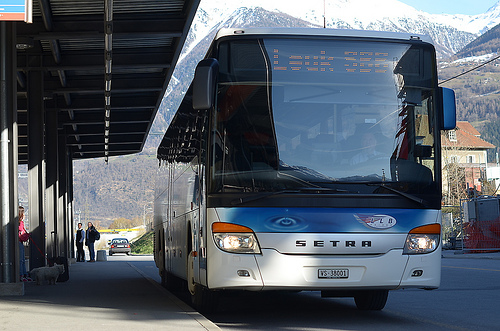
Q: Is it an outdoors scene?
A: Yes, it is outdoors.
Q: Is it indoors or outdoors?
A: It is outdoors.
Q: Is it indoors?
A: No, it is outdoors.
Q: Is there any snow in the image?
A: Yes, there is snow.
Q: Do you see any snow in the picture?
A: Yes, there is snow.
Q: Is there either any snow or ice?
A: Yes, there is snow.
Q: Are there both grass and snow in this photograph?
A: No, there is snow but no grass.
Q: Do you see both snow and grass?
A: No, there is snow but no grass.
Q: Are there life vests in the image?
A: No, there are no life vests.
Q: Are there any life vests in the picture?
A: No, there are no life vests.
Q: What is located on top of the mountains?
A: The snow is on top of the mountains.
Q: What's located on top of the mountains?
A: The snow is on top of the mountains.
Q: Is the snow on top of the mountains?
A: Yes, the snow is on top of the mountains.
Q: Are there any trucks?
A: No, there are no trucks.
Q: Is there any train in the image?
A: No, there are no trains.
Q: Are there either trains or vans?
A: No, there are no trains or vans.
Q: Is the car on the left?
A: Yes, the car is on the left of the image.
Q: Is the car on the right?
A: No, the car is on the left of the image.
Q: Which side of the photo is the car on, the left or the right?
A: The car is on the left of the image.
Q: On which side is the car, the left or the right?
A: The car is on the left of the image.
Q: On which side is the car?
A: The car is on the left of the image.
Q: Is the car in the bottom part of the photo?
A: Yes, the car is in the bottom of the image.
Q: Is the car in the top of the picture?
A: No, the car is in the bottom of the image.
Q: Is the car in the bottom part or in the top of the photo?
A: The car is in the bottom of the image.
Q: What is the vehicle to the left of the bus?
A: The vehicle is a car.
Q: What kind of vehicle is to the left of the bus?
A: The vehicle is a car.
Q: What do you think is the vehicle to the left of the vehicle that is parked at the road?
A: The vehicle is a car.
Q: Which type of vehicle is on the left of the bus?
A: The vehicle is a car.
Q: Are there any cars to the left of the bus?
A: Yes, there is a car to the left of the bus.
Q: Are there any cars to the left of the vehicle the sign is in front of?
A: Yes, there is a car to the left of the bus.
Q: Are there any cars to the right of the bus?
A: No, the car is to the left of the bus.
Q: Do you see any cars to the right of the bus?
A: No, the car is to the left of the bus.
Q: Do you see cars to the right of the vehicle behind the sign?
A: No, the car is to the left of the bus.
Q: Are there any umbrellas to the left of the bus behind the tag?
A: No, there is a car to the left of the bus.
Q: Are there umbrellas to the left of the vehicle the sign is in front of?
A: No, there is a car to the left of the bus.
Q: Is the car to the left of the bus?
A: Yes, the car is to the left of the bus.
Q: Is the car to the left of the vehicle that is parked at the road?
A: Yes, the car is to the left of the bus.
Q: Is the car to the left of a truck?
A: No, the car is to the left of the bus.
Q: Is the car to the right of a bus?
A: No, the car is to the left of a bus.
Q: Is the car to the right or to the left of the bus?
A: The car is to the left of the bus.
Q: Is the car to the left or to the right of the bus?
A: The car is to the left of the bus.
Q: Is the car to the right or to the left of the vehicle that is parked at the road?
A: The car is to the left of the bus.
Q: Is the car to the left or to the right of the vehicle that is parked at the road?
A: The car is to the left of the bus.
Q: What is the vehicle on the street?
A: The vehicle is a car.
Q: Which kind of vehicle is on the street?
A: The vehicle is a car.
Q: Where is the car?
A: The car is on the street.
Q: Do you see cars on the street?
A: Yes, there is a car on the street.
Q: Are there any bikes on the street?
A: No, there is a car on the street.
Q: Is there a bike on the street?
A: No, there is a car on the street.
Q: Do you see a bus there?
A: Yes, there is a bus.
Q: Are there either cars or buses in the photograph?
A: Yes, there is a bus.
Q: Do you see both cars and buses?
A: Yes, there are both a bus and a car.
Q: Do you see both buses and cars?
A: Yes, there are both a bus and a car.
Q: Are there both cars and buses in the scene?
A: Yes, there are both a bus and a car.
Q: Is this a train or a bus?
A: This is a bus.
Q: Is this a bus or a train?
A: This is a bus.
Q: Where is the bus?
A: The bus is on the road.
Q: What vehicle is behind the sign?
A: The vehicle is a bus.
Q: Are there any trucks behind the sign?
A: No, there is a bus behind the sign.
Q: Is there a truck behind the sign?
A: No, there is a bus behind the sign.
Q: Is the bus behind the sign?
A: Yes, the bus is behind the sign.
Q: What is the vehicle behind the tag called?
A: The vehicle is a bus.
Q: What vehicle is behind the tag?
A: The vehicle is a bus.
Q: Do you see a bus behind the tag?
A: Yes, there is a bus behind the tag.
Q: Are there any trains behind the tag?
A: No, there is a bus behind the tag.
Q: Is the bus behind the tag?
A: Yes, the bus is behind the tag.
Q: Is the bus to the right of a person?
A: Yes, the bus is to the right of a person.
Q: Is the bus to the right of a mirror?
A: No, the bus is to the right of a person.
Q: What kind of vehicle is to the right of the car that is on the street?
A: The vehicle is a bus.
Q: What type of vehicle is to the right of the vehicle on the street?
A: The vehicle is a bus.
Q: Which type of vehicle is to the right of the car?
A: The vehicle is a bus.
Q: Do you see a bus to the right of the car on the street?
A: Yes, there is a bus to the right of the car.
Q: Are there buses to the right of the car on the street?
A: Yes, there is a bus to the right of the car.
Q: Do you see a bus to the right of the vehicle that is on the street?
A: Yes, there is a bus to the right of the car.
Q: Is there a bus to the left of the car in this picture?
A: No, the bus is to the right of the car.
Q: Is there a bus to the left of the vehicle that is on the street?
A: No, the bus is to the right of the car.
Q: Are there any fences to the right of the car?
A: No, there is a bus to the right of the car.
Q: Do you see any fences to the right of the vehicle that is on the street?
A: No, there is a bus to the right of the car.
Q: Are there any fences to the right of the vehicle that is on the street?
A: No, there is a bus to the right of the car.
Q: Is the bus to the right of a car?
A: Yes, the bus is to the right of a car.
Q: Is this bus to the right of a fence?
A: No, the bus is to the right of a car.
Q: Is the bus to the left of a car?
A: No, the bus is to the right of a car.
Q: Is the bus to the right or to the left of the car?
A: The bus is to the right of the car.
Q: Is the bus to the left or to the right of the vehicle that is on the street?
A: The bus is to the right of the car.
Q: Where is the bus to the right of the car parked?
A: The bus is parked at the road.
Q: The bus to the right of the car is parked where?
A: The bus is parked at the road.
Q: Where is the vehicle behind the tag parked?
A: The bus is parked at the road.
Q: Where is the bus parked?
A: The bus is parked at the road.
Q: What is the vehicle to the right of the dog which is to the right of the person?
A: The vehicle is a bus.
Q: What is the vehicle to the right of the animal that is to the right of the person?
A: The vehicle is a bus.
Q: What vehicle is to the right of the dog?
A: The vehicle is a bus.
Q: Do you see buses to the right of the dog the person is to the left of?
A: Yes, there is a bus to the right of the dog.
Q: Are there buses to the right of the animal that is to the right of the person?
A: Yes, there is a bus to the right of the dog.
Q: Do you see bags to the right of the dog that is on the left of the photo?
A: No, there is a bus to the right of the dog.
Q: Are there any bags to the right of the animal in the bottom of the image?
A: No, there is a bus to the right of the dog.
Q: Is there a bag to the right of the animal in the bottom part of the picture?
A: No, there is a bus to the right of the dog.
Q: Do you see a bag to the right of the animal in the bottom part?
A: No, there is a bus to the right of the dog.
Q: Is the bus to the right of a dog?
A: Yes, the bus is to the right of a dog.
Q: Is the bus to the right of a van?
A: No, the bus is to the right of a dog.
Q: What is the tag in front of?
A: The tag is in front of the bus.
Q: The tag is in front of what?
A: The tag is in front of the bus.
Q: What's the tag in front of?
A: The tag is in front of the bus.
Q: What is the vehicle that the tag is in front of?
A: The vehicle is a bus.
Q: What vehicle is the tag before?
A: The tag is in front of the bus.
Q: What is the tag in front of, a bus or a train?
A: The tag is in front of a bus.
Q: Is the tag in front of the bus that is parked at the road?
A: Yes, the tag is in front of the bus.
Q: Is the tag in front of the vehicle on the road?
A: Yes, the tag is in front of the bus.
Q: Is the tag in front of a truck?
A: No, the tag is in front of the bus.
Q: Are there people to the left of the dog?
A: Yes, there is a person to the left of the dog.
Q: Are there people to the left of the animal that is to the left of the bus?
A: Yes, there is a person to the left of the dog.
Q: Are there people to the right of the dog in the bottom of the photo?
A: No, the person is to the left of the dog.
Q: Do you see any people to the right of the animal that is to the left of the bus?
A: No, the person is to the left of the dog.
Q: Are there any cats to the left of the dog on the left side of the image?
A: No, there is a person to the left of the dog.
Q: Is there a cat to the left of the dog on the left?
A: No, there is a person to the left of the dog.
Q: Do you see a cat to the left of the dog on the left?
A: No, there is a person to the left of the dog.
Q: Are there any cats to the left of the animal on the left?
A: No, there is a person to the left of the dog.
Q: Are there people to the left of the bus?
A: Yes, there is a person to the left of the bus.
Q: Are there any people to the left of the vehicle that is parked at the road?
A: Yes, there is a person to the left of the bus.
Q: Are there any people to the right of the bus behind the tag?
A: No, the person is to the left of the bus.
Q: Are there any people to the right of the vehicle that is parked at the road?
A: No, the person is to the left of the bus.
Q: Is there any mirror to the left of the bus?
A: No, there is a person to the left of the bus.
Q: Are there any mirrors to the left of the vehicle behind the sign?
A: No, there is a person to the left of the bus.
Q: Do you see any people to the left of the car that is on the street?
A: Yes, there is a person to the left of the car.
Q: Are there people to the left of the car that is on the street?
A: Yes, there is a person to the left of the car.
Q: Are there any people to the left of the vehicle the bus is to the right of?
A: Yes, there is a person to the left of the car.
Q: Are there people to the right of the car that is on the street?
A: No, the person is to the left of the car.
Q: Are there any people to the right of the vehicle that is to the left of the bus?
A: No, the person is to the left of the car.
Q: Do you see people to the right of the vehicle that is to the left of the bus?
A: No, the person is to the left of the car.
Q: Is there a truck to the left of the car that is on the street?
A: No, there is a person to the left of the car.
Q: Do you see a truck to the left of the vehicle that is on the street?
A: No, there is a person to the left of the car.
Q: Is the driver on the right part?
A: Yes, the driver is on the right of the image.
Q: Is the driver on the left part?
A: No, the driver is on the right of the image.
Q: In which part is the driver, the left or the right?
A: The driver is on the right of the image.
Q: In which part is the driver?
A: The driver is on the right of the image.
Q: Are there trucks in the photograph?
A: No, there are no trucks.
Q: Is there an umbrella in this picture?
A: No, there are no umbrellas.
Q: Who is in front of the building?
A: The people are in front of the building.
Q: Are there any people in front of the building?
A: Yes, there are people in front of the building.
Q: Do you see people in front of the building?
A: Yes, there are people in front of the building.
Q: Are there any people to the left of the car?
A: Yes, there are people to the left of the car.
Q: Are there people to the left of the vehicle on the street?
A: Yes, there are people to the left of the car.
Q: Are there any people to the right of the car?
A: No, the people are to the left of the car.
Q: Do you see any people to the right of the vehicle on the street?
A: No, the people are to the left of the car.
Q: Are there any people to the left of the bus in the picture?
A: Yes, there are people to the left of the bus.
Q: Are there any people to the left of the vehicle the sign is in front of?
A: Yes, there are people to the left of the bus.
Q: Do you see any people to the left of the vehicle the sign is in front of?
A: Yes, there are people to the left of the bus.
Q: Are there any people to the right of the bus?
A: No, the people are to the left of the bus.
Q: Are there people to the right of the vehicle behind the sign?
A: No, the people are to the left of the bus.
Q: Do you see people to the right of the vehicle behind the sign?
A: No, the people are to the left of the bus.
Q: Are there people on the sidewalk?
A: Yes, there are people on the sidewalk.